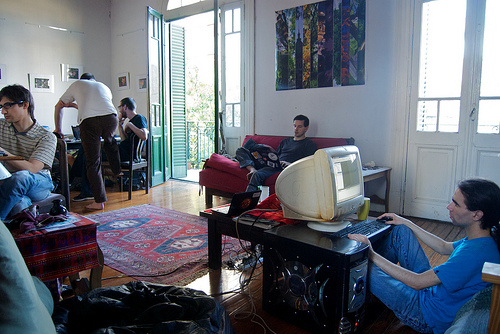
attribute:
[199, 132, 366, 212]
sofa — red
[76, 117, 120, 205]
pants — dark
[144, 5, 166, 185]
door — green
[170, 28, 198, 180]
door — open, green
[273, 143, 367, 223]
monitor — white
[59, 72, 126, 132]
shirt — white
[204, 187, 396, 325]
table — black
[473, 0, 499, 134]
window — long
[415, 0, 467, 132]
window — long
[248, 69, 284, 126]
wall — white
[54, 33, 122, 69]
wall — white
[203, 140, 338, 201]
couch — red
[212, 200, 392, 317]
table — dark brown, wood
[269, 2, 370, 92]
painting — a collage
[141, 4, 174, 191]
door — large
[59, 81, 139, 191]
body — bending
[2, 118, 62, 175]
shirt — striped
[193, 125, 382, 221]
couch — red